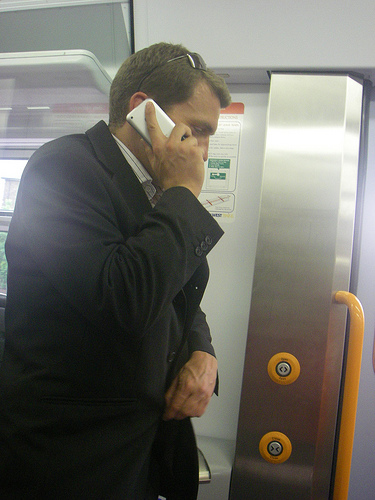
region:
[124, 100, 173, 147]
the phone is white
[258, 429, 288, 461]
the circle is orange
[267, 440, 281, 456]
the circle is silver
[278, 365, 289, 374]
black lines in circle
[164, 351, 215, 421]
the hand of a man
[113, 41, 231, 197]
man talking on phone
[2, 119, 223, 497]
the suit is black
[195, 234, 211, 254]
the buttons are black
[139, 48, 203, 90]
glasses on man's head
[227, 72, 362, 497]
the column is silver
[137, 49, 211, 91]
sunglasses on a man's head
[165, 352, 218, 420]
a man's hand unbuttoning a jacket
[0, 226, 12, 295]
a window behind a man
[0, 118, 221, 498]
a suit jacket on a man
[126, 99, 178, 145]
a white phone in a man's hand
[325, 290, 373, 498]
a yellow handle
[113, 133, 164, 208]
a white shirt with pin stripes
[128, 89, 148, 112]
the ear of a man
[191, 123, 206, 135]
the eye of a man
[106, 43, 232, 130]
light brown hair on a man's head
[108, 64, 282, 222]
a man on a phone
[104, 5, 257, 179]
a man on a cell phone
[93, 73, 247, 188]
a man holding a phone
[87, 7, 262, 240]
a man holding a cell phone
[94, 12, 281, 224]
a man talking on a phone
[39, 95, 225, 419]
a man wearing suit jacket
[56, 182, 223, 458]
a suit jacket that is black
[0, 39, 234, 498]
a man in a black jacket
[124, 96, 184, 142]
a grey cellphone being held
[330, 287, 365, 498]
a yellow metal handrail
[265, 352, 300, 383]
a button on the wall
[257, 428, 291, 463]
a button on the wall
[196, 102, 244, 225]
a sign on the wall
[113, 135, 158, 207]
a white striped shirt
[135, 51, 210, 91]
a pair of sunglasses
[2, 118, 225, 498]
a large black coat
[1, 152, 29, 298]
A window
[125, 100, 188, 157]
the man is on the phone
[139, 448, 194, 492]
part of black jacket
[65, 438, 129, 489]
part of black jacket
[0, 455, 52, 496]
part of black jacket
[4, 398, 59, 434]
part of black jacket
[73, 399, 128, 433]
part of black jacket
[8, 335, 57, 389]
part of black jacket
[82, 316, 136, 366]
part of black jacket